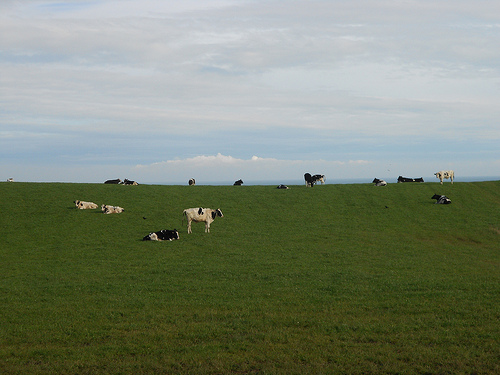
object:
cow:
[434, 170, 454, 185]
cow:
[431, 194, 452, 204]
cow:
[101, 204, 125, 215]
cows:
[73, 200, 124, 215]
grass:
[0, 181, 500, 375]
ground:
[0, 182, 500, 375]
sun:
[0, 0, 493, 189]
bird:
[143, 217, 148, 220]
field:
[0, 180, 500, 375]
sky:
[1, 2, 499, 188]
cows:
[143, 207, 224, 241]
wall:
[114, 122, 264, 189]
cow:
[143, 229, 180, 243]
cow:
[73, 200, 99, 210]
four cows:
[73, 200, 223, 242]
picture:
[1, 3, 496, 373]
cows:
[73, 169, 454, 242]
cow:
[182, 207, 224, 234]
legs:
[187, 218, 210, 232]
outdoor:
[0, 0, 499, 374]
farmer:
[7, 177, 14, 182]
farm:
[0, 183, 500, 375]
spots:
[193, 207, 207, 215]